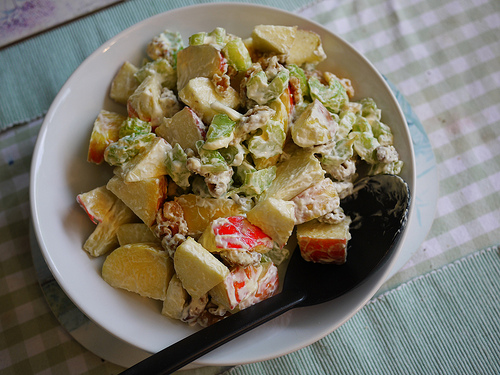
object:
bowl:
[30, 2, 417, 366]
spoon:
[118, 171, 410, 374]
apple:
[294, 215, 352, 263]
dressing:
[76, 24, 404, 327]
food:
[199, 109, 235, 152]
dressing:
[340, 173, 410, 236]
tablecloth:
[0, 1, 499, 374]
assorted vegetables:
[77, 24, 403, 328]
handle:
[118, 293, 302, 374]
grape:
[219, 37, 252, 71]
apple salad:
[74, 25, 404, 326]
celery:
[249, 120, 285, 158]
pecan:
[151, 200, 189, 260]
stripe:
[361, 1, 499, 64]